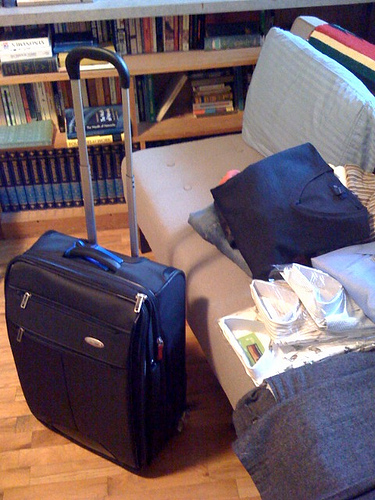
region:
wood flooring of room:
[5, 230, 205, 496]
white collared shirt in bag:
[226, 310, 291, 385]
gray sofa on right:
[122, 102, 374, 365]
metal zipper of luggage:
[20, 284, 31, 305]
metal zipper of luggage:
[10, 328, 24, 337]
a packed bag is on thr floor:
[27, 161, 196, 494]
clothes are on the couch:
[240, 190, 373, 392]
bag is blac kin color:
[25, 207, 160, 384]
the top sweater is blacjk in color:
[248, 168, 341, 256]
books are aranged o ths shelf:
[10, 71, 133, 234]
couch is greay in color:
[155, 73, 347, 134]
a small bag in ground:
[2, 224, 210, 481]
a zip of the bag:
[127, 291, 155, 321]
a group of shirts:
[226, 263, 364, 389]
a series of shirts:
[217, 251, 372, 372]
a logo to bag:
[69, 319, 112, 356]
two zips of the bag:
[7, 270, 165, 339]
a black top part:
[71, 30, 144, 84]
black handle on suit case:
[64, 40, 134, 83]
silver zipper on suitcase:
[127, 294, 150, 322]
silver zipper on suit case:
[13, 292, 29, 314]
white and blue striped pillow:
[227, 36, 367, 183]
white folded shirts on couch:
[232, 261, 343, 357]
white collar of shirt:
[215, 309, 277, 370]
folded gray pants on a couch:
[231, 350, 374, 499]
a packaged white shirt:
[273, 262, 373, 337]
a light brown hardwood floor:
[0, 212, 260, 499]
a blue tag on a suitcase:
[63, 240, 125, 269]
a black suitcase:
[3, 229, 188, 472]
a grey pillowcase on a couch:
[240, 26, 374, 170]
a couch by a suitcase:
[121, 16, 372, 499]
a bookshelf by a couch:
[0, 1, 373, 235]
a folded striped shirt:
[344, 161, 374, 240]